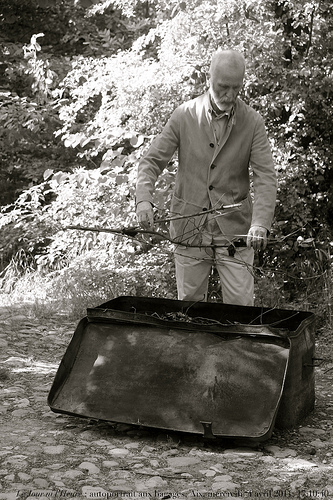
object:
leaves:
[14, 38, 52, 99]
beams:
[31, 65, 123, 247]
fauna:
[0, 0, 332, 296]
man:
[135, 48, 277, 306]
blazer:
[135, 89, 278, 251]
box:
[47, 295, 316, 448]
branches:
[69, 223, 245, 255]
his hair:
[208, 48, 246, 80]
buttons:
[208, 142, 215, 148]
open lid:
[47, 314, 292, 444]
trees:
[0, 0, 332, 316]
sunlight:
[15, 0, 208, 221]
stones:
[0, 313, 25, 329]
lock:
[200, 419, 216, 445]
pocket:
[222, 200, 251, 232]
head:
[205, 48, 246, 112]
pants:
[172, 242, 255, 306]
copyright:
[15, 486, 332, 499]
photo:
[0, 0, 332, 500]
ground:
[0, 441, 333, 499]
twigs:
[103, 303, 300, 333]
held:
[62, 200, 319, 284]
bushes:
[278, 0, 332, 235]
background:
[0, 0, 332, 362]